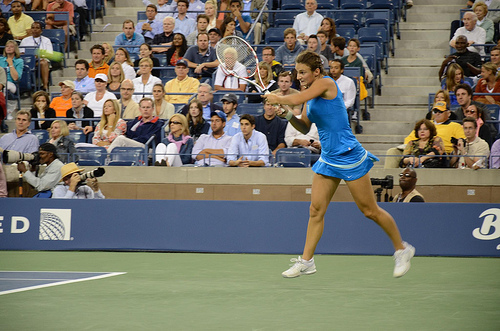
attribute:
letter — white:
[7, 214, 32, 236]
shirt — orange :
[50, 86, 77, 118]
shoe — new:
[280, 257, 318, 277]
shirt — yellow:
[294, 82, 430, 177]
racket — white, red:
[225, 39, 289, 102]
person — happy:
[457, 117, 491, 169]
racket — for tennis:
[215, 33, 287, 113]